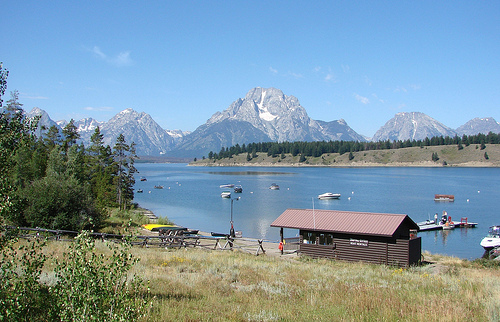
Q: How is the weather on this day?
A: It is clear.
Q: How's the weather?
A: It is clear.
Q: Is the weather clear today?
A: Yes, it is clear.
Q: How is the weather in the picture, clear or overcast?
A: It is clear.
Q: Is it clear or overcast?
A: It is clear.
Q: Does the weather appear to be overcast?
A: No, it is clear.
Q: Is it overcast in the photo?
A: No, it is clear.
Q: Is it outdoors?
A: Yes, it is outdoors.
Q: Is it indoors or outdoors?
A: It is outdoors.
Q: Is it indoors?
A: No, it is outdoors.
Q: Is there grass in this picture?
A: Yes, there is grass.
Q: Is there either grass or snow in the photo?
A: Yes, there is grass.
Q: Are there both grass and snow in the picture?
A: Yes, there are both grass and snow.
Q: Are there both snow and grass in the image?
A: Yes, there are both grass and snow.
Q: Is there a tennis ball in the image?
A: No, there are no tennis balls.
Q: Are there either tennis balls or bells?
A: No, there are no tennis balls or bells.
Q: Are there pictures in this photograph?
A: No, there are no pictures.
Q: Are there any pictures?
A: No, there are no pictures.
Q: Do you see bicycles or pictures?
A: No, there are no pictures or bicycles.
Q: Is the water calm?
A: Yes, the water is calm.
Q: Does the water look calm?
A: Yes, the water is calm.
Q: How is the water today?
A: The water is calm.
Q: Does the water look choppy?
A: No, the water is calm.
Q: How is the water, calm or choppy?
A: The water is calm.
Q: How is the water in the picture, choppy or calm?
A: The water is calm.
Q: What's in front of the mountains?
A: The water is in front of the mountains.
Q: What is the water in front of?
A: The water is in front of the mountains.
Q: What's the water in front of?
A: The water is in front of the mountains.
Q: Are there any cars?
A: No, there are no cars.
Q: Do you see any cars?
A: No, there are no cars.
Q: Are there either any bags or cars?
A: No, there are no cars or bags.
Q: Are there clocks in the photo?
A: No, there are no clocks.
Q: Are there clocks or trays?
A: No, there are no clocks or trays.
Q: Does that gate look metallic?
A: Yes, the gate is metallic.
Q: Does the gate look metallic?
A: Yes, the gate is metallic.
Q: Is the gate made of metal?
A: Yes, the gate is made of metal.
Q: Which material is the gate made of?
A: The gate is made of metal.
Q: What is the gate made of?
A: The gate is made of metal.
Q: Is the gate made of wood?
A: No, the gate is made of metal.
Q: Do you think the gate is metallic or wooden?
A: The gate is metallic.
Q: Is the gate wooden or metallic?
A: The gate is metallic.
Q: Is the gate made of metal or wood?
A: The gate is made of metal.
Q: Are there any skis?
A: No, there are no skis.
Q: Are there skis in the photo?
A: No, there are no skis.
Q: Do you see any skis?
A: No, there are no skis.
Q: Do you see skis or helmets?
A: No, there are no skis or helmets.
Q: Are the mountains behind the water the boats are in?
A: Yes, the mountains are behind the water.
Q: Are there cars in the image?
A: No, there are no cars.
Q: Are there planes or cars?
A: No, there are no cars or planes.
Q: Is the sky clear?
A: Yes, the sky is clear.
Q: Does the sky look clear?
A: Yes, the sky is clear.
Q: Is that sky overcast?
A: No, the sky is clear.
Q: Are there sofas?
A: No, there are no sofas.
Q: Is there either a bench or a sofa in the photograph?
A: No, there are no sofas or benches.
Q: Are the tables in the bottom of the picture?
A: Yes, the tables are in the bottom of the image.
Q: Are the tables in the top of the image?
A: No, the tables are in the bottom of the image.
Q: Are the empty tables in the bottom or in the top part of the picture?
A: The tables are in the bottom of the image.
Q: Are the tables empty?
A: Yes, the tables are empty.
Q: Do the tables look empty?
A: Yes, the tables are empty.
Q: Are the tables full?
A: No, the tables are empty.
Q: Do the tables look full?
A: No, the tables are empty.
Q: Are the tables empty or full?
A: The tables are empty.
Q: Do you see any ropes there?
A: No, there are no ropes.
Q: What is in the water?
A: The boats are in the water.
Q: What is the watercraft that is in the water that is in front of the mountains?
A: The watercraft is boats.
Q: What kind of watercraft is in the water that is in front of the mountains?
A: The watercraft is boats.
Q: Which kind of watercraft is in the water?
A: The watercraft is boats.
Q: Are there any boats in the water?
A: Yes, there are boats in the water.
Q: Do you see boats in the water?
A: Yes, there are boats in the water.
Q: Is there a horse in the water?
A: No, there are boats in the water.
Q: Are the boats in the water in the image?
A: Yes, the boats are in the water.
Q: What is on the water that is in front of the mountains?
A: The boats are on the water.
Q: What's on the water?
A: The boats are on the water.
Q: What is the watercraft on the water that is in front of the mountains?
A: The watercraft is boats.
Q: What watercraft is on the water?
A: The watercraft is boats.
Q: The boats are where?
A: The boats are on the water.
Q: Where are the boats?
A: The boats are on the water.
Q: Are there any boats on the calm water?
A: Yes, there are boats on the water.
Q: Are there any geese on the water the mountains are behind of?
A: No, there are boats on the water.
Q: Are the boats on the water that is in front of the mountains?
A: Yes, the boats are on the water.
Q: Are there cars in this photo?
A: No, there are no cars.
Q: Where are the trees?
A: The trees are on the shore.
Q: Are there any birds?
A: No, there are no birds.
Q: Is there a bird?
A: No, there are no birds.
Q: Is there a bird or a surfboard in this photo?
A: No, there are no birds or surfboards.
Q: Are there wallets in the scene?
A: No, there are no wallets.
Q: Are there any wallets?
A: No, there are no wallets.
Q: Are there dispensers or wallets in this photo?
A: No, there are no wallets or dispensers.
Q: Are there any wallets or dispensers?
A: No, there are no wallets or dispensers.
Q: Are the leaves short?
A: Yes, the leaves are short.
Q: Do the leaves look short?
A: Yes, the leaves are short.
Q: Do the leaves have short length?
A: Yes, the leaves are short.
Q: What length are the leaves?
A: The leaves are short.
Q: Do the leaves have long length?
A: No, the leaves are short.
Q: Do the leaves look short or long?
A: The leaves are short.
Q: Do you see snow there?
A: Yes, there is snow.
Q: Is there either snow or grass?
A: Yes, there is snow.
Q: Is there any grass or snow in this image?
A: Yes, there is snow.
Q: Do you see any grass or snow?
A: Yes, there is snow.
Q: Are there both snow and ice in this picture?
A: No, there is snow but no ice.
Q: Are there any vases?
A: No, there are no vases.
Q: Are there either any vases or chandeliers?
A: No, there are no vases or chandeliers.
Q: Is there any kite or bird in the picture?
A: No, there are no birds or kites.